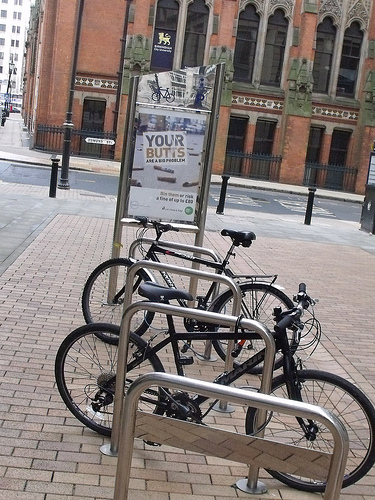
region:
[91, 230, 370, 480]
two bikes in storage racks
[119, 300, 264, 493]
storage rack is metallic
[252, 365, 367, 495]
bike wheel is black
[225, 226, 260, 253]
bike seat is black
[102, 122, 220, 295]
sign supports are metallic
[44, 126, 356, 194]
black fence in background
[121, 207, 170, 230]
bike handlebars are black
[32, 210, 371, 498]
sidewalk is cobblestone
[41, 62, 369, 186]
building is red brick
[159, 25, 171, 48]
gold lion on banner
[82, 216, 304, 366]
a parked black bike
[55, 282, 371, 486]
a parked black bike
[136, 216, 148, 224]
the black rubber handle of the bike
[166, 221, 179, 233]
the black rubber handle of the bike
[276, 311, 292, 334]
the black rubber handle of the bike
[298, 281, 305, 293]
the black rubber handle of the bike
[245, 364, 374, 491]
the large wheel of the bike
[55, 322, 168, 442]
the large wheel of the bike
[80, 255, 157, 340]
the large wheel of the bike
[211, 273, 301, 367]
the large wheel of the bike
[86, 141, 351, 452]
bikes chained to rack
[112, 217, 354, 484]
a metal bike rack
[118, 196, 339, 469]
two bikes chained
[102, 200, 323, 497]
bikes on a sidewalk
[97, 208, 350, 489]
bike rack on a sidewalk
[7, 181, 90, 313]
a brick sidewalk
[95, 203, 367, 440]
bikes standing up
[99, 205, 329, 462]
two black bikes standing up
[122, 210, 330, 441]
bikes standing up outside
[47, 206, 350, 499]
silver metal bike rack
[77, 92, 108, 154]
a long glass door of the building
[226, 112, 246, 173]
a long glass door of the building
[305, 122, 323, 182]
a long glass door of the building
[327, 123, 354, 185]
a long glass door of the building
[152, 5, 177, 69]
a long glass window of the building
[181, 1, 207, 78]
a long glass window of the building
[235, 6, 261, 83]
a long glass window of the building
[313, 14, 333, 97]
a long glass window of the building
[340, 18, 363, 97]
a long glass window of the building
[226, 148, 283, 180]
black metal picket fence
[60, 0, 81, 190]
black metal lamp post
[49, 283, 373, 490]
black mountain bike on sidewalk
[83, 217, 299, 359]
blackbike with silver writing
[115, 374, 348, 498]
silver metal bike rack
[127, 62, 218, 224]
sign connected on metal posts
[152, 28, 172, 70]
blue banner on building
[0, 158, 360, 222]
black asphalt rode way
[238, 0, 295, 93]
stone and glass windows on building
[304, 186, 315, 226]
black metal post on sidewalk